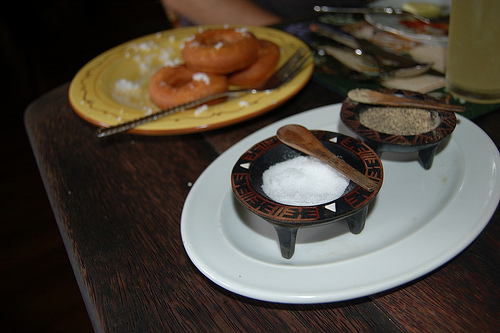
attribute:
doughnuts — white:
[147, 25, 284, 110]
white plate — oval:
[178, 88, 496, 304]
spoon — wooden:
[300, 85, 467, 113]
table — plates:
[104, 230, 171, 311]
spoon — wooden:
[276, 121, 383, 198]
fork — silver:
[92, 46, 314, 138]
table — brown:
[65, 174, 154, 304]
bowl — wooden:
[340, 83, 460, 170]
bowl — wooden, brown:
[239, 126, 387, 261]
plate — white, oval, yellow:
[177, 94, 499, 300]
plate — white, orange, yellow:
[69, 27, 307, 138]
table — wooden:
[55, 154, 260, 326]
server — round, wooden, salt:
[231, 129, 383, 258]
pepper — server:
[345, 90, 460, 172]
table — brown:
[23, 89, 497, 326]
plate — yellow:
[52, 29, 318, 136]